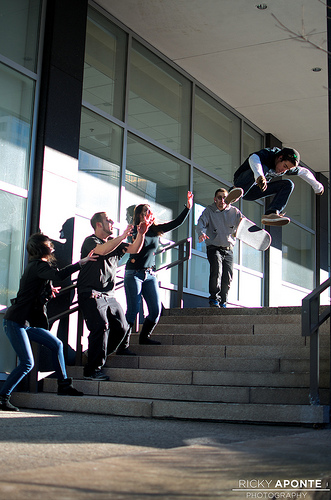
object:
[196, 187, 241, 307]
man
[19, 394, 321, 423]
staircase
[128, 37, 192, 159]
window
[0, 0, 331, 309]
building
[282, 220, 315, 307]
door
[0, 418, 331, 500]
sidewalk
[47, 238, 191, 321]
rail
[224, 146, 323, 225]
man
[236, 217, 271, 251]
skateboard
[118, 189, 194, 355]
woman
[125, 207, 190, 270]
sweater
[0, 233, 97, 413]
woman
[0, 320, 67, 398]
jeans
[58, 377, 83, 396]
boots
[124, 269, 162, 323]
jeans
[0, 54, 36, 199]
window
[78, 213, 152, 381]
man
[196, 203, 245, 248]
sweatshirt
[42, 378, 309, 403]
step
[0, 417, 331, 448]
shadow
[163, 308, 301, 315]
step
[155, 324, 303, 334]
step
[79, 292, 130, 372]
jeans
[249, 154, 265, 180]
sleeve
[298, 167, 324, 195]
sleeve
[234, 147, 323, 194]
t-shirt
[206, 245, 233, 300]
pants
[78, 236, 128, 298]
shirt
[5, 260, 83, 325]
sweatshirt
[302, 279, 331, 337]
rail